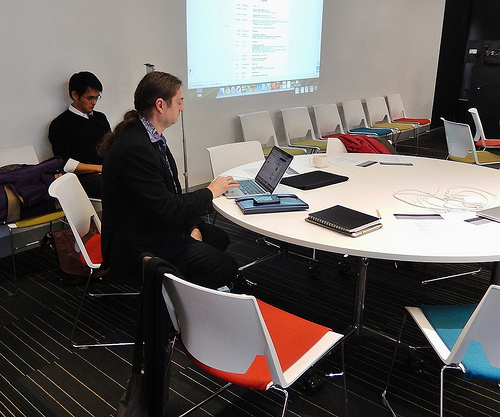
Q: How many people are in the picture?
A: Two.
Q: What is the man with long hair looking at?
A: Laptop.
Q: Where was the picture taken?
A: Office.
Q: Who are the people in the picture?
A: Office workers.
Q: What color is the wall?
A: White.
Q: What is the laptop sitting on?
A: Table.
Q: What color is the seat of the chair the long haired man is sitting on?
A: Orange.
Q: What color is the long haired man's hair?
A: Brown.